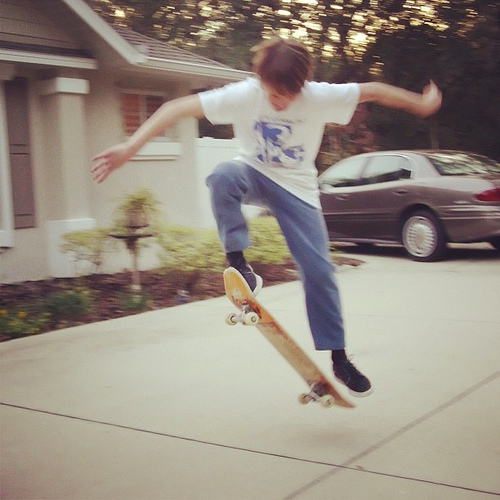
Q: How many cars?
A: One.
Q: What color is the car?
A: Grey.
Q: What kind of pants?
A: Jeans.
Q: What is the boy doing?
A: Skateboarding.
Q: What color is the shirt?
A: White and blue.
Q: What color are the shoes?
A: Black.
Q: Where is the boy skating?
A: Driveway.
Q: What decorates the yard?
A: Plants.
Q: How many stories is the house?
A: One.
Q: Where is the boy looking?
A: Down.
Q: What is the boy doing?
A: Skateboard.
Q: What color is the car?
A: Gray.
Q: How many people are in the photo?
A: 1.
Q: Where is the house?
A: Behind the skateboarder.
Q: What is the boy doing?
A: Skateboarding.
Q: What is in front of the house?
A: Plants.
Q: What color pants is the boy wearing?
A: Blue.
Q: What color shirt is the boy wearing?
A: White.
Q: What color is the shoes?
A: Black.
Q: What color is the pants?
A: Blue.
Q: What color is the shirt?
A: White.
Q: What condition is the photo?
A: Blurry.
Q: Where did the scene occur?
A: Outside near house.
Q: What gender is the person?
A: Boy.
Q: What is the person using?
A: Skateboard.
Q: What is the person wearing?
A: Shirt and jeans.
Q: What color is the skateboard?
A: Brown.